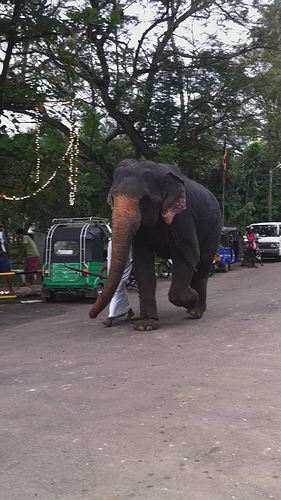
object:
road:
[0, 261, 281, 499]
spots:
[141, 407, 221, 490]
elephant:
[88, 161, 220, 332]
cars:
[44, 219, 130, 296]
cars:
[249, 223, 281, 256]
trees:
[0, 0, 279, 245]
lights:
[0, 106, 80, 207]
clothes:
[106, 238, 134, 323]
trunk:
[87, 198, 142, 319]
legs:
[131, 249, 209, 333]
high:
[168, 258, 198, 308]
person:
[104, 224, 136, 326]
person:
[246, 227, 257, 255]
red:
[247, 234, 253, 245]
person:
[15, 229, 39, 286]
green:
[19, 234, 37, 256]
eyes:
[110, 195, 149, 205]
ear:
[163, 173, 187, 225]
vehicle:
[209, 230, 235, 274]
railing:
[45, 217, 90, 279]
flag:
[221, 141, 226, 178]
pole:
[221, 180, 225, 235]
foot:
[132, 318, 160, 331]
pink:
[163, 191, 188, 223]